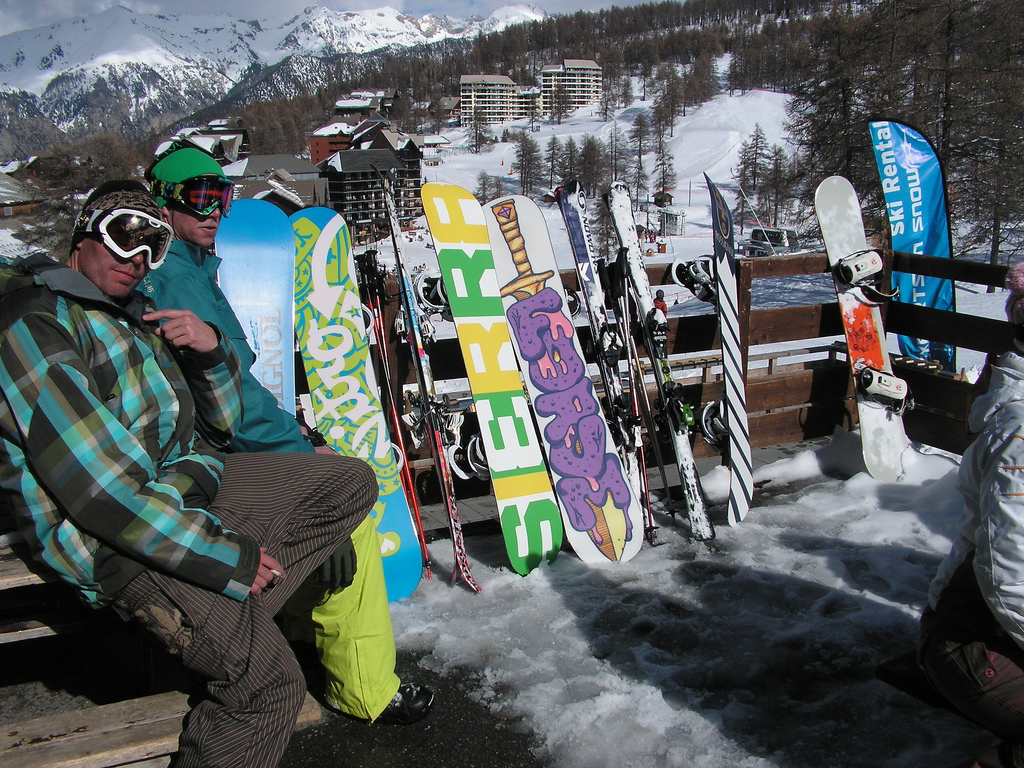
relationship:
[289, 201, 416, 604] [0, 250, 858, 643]
snowboard leaning on fence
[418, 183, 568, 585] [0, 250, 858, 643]
snowboard leaning on fence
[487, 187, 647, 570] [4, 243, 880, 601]
snowboard leaning on fence